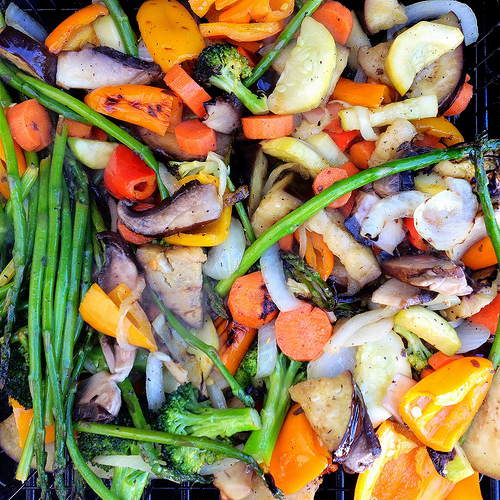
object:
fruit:
[264, 407, 331, 496]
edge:
[279, 458, 331, 496]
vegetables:
[0, 104, 27, 312]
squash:
[385, 18, 465, 98]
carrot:
[226, 271, 278, 330]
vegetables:
[354, 419, 484, 500]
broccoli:
[194, 44, 270, 116]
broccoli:
[75, 420, 136, 474]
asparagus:
[75, 243, 92, 344]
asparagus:
[53, 178, 69, 368]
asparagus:
[43, 123, 64, 425]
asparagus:
[28, 153, 49, 475]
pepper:
[398, 357, 495, 452]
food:
[287, 371, 380, 474]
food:
[215, 139, 500, 300]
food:
[77, 281, 156, 352]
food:
[412, 178, 478, 251]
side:
[471, 0, 500, 496]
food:
[6, 98, 52, 152]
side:
[1, 0, 39, 497]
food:
[203, 218, 245, 281]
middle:
[252, 243, 298, 313]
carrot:
[274, 301, 332, 361]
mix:
[0, 2, 498, 497]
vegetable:
[156, 382, 263, 478]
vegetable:
[136, 0, 207, 74]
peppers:
[269, 404, 329, 495]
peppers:
[164, 174, 232, 247]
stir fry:
[0, 0, 500, 500]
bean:
[71, 424, 264, 484]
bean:
[17, 72, 166, 200]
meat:
[135, 243, 205, 330]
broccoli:
[242, 350, 303, 463]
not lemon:
[266, 12, 337, 115]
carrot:
[175, 121, 217, 155]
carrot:
[241, 115, 293, 140]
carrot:
[312, 166, 352, 208]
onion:
[261, 243, 303, 313]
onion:
[146, 351, 170, 409]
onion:
[405, 0, 480, 47]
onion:
[257, 319, 277, 380]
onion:
[321, 307, 393, 354]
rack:
[1, 1, 499, 497]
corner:
[437, 443, 500, 500]